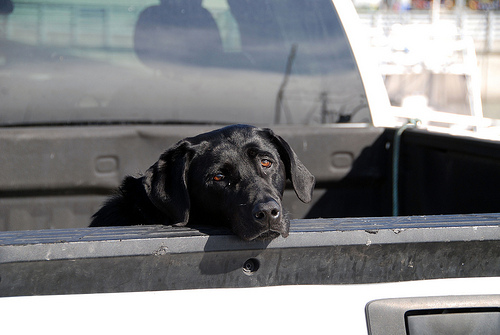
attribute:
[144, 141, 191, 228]
ear — floppy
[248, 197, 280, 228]
nose — black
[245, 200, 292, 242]
muzzle — black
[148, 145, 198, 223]
ear — black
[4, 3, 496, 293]
truck — white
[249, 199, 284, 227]
nose — black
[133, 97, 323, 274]
dog — black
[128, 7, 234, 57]
headrest — passenger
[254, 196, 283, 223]
nose — black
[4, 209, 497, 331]
tailgate — open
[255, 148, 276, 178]
eye — brown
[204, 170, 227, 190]
eye — brown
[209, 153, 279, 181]
eyes — sad